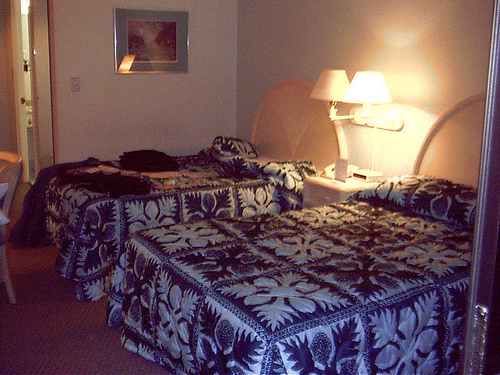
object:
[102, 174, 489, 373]
bed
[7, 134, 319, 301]
bed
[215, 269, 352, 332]
snowflake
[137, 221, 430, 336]
covers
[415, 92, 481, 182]
head board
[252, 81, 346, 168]
headboard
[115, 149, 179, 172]
bag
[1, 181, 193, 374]
carpet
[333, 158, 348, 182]
telephone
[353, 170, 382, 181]
clock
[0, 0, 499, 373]
bedroom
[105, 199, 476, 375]
quilt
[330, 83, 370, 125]
ground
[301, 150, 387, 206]
red bus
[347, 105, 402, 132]
light table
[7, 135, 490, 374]
comforter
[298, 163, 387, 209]
desk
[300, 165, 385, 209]
table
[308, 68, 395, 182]
lamps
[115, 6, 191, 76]
picture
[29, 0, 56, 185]
mirror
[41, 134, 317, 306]
covers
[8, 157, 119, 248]
clothes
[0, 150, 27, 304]
seat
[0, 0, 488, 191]
wall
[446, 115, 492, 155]
wood